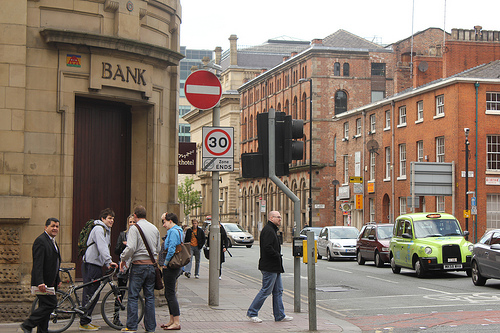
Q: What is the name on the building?
A: BANK.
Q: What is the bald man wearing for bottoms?
A: Jeans.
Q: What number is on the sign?
A: 30.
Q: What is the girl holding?
A: A purse.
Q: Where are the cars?
A: In the street.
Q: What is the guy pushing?
A: A bicycle.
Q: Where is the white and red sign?
A: On the pole.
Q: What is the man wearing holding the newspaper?
A: A suit.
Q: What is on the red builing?
A: A red building with lots of windows.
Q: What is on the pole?
A: Street signs on a pole.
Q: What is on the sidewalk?
A: Group of people on the sidewalk.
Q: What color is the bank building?
A: Tan.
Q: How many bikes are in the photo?
A: 1.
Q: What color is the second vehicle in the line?
A: Green.